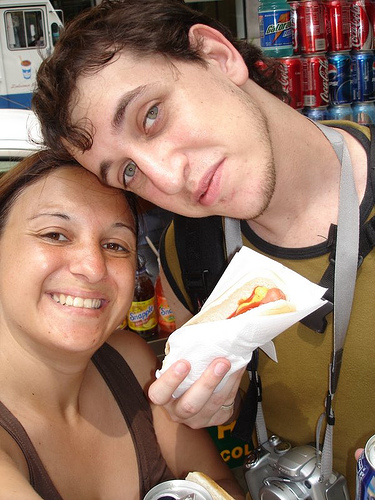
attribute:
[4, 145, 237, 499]
woman — smiling, young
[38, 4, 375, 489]
man — young, leaning, holding can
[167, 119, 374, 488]
yellow shirt — green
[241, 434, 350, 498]
camera — silver, on strap, gray, digital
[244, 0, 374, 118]
can — red can, coke, assorted, soda, red, for drinking, aluminum, coco cola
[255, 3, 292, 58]
bottles — gatorade, bottled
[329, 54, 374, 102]
can — pepsi, aluminum, blue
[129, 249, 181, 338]
bottles — snapple, glass, orange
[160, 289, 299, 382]
hotdog — topped with mustard, topped with ketchup, on a bun, wrapped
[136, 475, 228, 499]
can — open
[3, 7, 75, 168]
truck — white, ice cream truck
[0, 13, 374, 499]
couple — smiling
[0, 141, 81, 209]
hair — brown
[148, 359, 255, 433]
hand — holding frank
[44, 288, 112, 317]
smile — big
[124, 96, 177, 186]
eyes — gray, blue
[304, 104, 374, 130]
can — diet